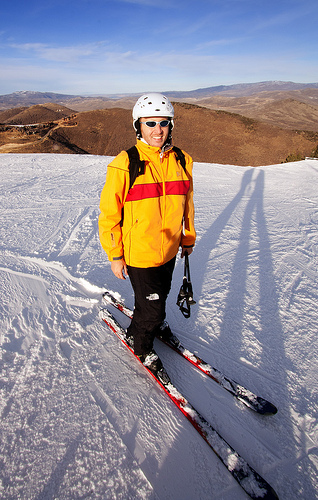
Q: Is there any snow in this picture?
A: Yes, there is snow.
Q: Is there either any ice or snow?
A: Yes, there is snow.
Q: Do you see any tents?
A: No, there are no tents.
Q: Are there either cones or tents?
A: No, there are no tents or cones.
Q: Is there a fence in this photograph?
A: No, there are no fences.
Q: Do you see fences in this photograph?
A: No, there are no fences.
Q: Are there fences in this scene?
A: No, there are no fences.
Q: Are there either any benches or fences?
A: No, there are no fences or benches.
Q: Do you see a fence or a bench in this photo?
A: No, there are no fences or benches.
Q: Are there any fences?
A: No, there are no fences.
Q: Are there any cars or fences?
A: No, there are no fences or cars.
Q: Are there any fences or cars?
A: No, there are no fences or cars.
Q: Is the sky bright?
A: Yes, the sky is bright.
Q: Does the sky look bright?
A: Yes, the sky is bright.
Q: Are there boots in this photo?
A: Yes, there are boots.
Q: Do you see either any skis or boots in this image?
A: Yes, there are boots.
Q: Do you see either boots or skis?
A: Yes, there are boots.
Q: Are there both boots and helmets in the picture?
A: Yes, there are both boots and a helmet.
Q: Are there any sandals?
A: No, there are no sandals.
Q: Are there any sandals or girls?
A: No, there are no sandals or girls.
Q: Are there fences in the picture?
A: No, there are no fences.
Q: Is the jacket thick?
A: Yes, the jacket is thick.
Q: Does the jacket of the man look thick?
A: Yes, the jacket is thick.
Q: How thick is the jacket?
A: The jacket is thick.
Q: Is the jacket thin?
A: No, the jacket is thick.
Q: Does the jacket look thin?
A: No, the jacket is thick.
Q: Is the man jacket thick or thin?
A: The jacket is thick.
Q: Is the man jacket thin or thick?
A: The jacket is thick.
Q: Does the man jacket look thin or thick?
A: The jacket is thick.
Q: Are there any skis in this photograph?
A: Yes, there are skis.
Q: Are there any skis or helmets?
A: Yes, there are skis.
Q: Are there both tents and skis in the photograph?
A: No, there are skis but no tents.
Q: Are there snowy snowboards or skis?
A: Yes, there are snowy skis.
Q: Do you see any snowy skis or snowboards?
A: Yes, there are snowy skis.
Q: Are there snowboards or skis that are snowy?
A: Yes, the skis are snowy.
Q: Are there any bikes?
A: No, there are no bikes.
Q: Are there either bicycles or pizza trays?
A: No, there are no bicycles or pizza trays.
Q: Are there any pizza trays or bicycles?
A: No, there are no bicycles or pizza trays.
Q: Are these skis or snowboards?
A: These are skis.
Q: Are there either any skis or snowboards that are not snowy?
A: No, there are skis but they are snowy.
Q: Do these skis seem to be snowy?
A: Yes, the skis are snowy.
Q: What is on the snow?
A: The skis are on the snow.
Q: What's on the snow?
A: The skis are on the snow.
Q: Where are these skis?
A: The skis are on the snow.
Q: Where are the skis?
A: The skis are on the snow.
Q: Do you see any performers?
A: No, there are no performers.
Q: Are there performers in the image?
A: No, there are no performers.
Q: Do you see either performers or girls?
A: No, there are no performers or girls.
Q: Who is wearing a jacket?
A: The man is wearing a jacket.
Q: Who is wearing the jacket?
A: The man is wearing a jacket.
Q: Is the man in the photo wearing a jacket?
A: Yes, the man is wearing a jacket.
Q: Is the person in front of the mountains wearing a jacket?
A: Yes, the man is wearing a jacket.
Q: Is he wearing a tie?
A: No, the man is wearing a jacket.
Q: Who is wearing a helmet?
A: The man is wearing a helmet.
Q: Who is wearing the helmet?
A: The man is wearing a helmet.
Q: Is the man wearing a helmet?
A: Yes, the man is wearing a helmet.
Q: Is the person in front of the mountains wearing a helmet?
A: Yes, the man is wearing a helmet.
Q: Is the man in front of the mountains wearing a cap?
A: No, the man is wearing a helmet.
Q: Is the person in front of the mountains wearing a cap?
A: No, the man is wearing a helmet.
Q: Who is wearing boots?
A: The man is wearing boots.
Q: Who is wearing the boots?
A: The man is wearing boots.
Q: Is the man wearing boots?
A: Yes, the man is wearing boots.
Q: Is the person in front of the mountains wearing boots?
A: Yes, the man is wearing boots.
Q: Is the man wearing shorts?
A: No, the man is wearing boots.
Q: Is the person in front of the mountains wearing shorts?
A: No, the man is wearing boots.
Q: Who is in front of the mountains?
A: The man is in front of the mountains.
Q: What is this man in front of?
A: The man is in front of the mountains.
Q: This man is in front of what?
A: The man is in front of the mountains.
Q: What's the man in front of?
A: The man is in front of the mountains.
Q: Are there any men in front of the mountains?
A: Yes, there is a man in front of the mountains.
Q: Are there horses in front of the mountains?
A: No, there is a man in front of the mountains.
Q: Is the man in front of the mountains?
A: Yes, the man is in front of the mountains.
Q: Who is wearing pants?
A: The man is wearing pants.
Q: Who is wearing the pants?
A: The man is wearing pants.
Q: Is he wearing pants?
A: Yes, the man is wearing pants.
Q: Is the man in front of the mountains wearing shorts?
A: No, the man is wearing pants.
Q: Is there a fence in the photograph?
A: No, there are no fences.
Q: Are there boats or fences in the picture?
A: No, there are no fences or boats.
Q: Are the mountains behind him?
A: Yes, the mountains are behind a man.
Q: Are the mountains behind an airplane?
A: No, the mountains are behind a man.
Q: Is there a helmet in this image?
A: Yes, there is a helmet.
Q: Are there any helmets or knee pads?
A: Yes, there is a helmet.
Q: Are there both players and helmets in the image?
A: No, there is a helmet but no players.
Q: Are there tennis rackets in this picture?
A: No, there are no tennis rackets.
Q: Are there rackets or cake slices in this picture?
A: No, there are no rackets or cake slices.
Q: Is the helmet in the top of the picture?
A: Yes, the helmet is in the top of the image.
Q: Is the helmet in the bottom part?
A: No, the helmet is in the top of the image.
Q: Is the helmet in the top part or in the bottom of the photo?
A: The helmet is in the top of the image.